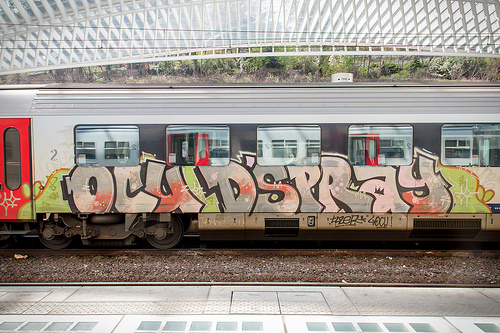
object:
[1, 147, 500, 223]
graffiti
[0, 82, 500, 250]
train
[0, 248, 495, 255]
train track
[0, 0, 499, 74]
fence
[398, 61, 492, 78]
bushes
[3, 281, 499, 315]
ground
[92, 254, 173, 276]
gravel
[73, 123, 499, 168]
five windows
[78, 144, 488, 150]
each other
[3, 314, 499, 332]
fifteen squares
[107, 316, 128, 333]
lines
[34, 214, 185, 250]
wheels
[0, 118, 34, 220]
door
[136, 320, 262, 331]
stone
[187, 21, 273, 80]
trees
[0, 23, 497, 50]
square lines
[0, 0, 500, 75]
ceiling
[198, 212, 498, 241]
bracket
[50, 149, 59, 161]
number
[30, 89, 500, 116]
grey lines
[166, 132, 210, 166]
open door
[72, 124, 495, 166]
other train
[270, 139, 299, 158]
window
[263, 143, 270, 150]
number